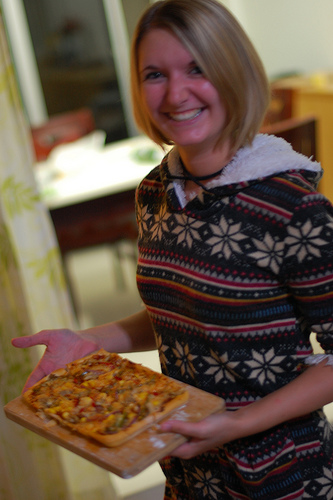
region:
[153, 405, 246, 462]
the hand of a woman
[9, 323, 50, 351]
the thumb of a woman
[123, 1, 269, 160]
the head of a woman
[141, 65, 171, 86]
the eye of a woman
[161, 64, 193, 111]
the nose of a woman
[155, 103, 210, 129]
the mouth of a woman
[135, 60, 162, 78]
the eyebrow of a woman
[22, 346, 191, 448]
a pizza on the tray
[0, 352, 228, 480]
a brown wooden tray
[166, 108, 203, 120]
the teeth of a woman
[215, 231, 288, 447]
a woman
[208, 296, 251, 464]
a woman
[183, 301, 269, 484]
a woman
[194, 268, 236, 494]
a woman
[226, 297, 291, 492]
a woman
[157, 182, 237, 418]
a woman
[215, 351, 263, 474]
a woman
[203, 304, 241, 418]
a woman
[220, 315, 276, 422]
a woman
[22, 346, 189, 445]
a rectangular pizza on a cutting board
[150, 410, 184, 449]
white flour on a cutting board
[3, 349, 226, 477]
a rectangular wooden cutting board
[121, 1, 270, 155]
short blond hair on a woman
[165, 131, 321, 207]
a fuzzy hood on a woman's dress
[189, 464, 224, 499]
a white flower pattern on a dress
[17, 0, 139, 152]
an open doorway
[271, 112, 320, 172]
the back of a wooden chair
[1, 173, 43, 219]
a green pattern on a white wall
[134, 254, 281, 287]
a red stripe on a dress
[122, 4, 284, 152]
woman with short blonde hair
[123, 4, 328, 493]
young lady wearing a winter sweater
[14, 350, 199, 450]
a square home made pizza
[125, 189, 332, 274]
snowflake design on a sweater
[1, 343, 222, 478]
a wood cutting board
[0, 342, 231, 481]
home made pizza on a cutting board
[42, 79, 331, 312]
three chairs sitting around a table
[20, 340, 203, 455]
home made pizza with meat toppings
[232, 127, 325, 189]
white fuzzy inside of a hood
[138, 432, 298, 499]
two pockets on the bottom of the sweater